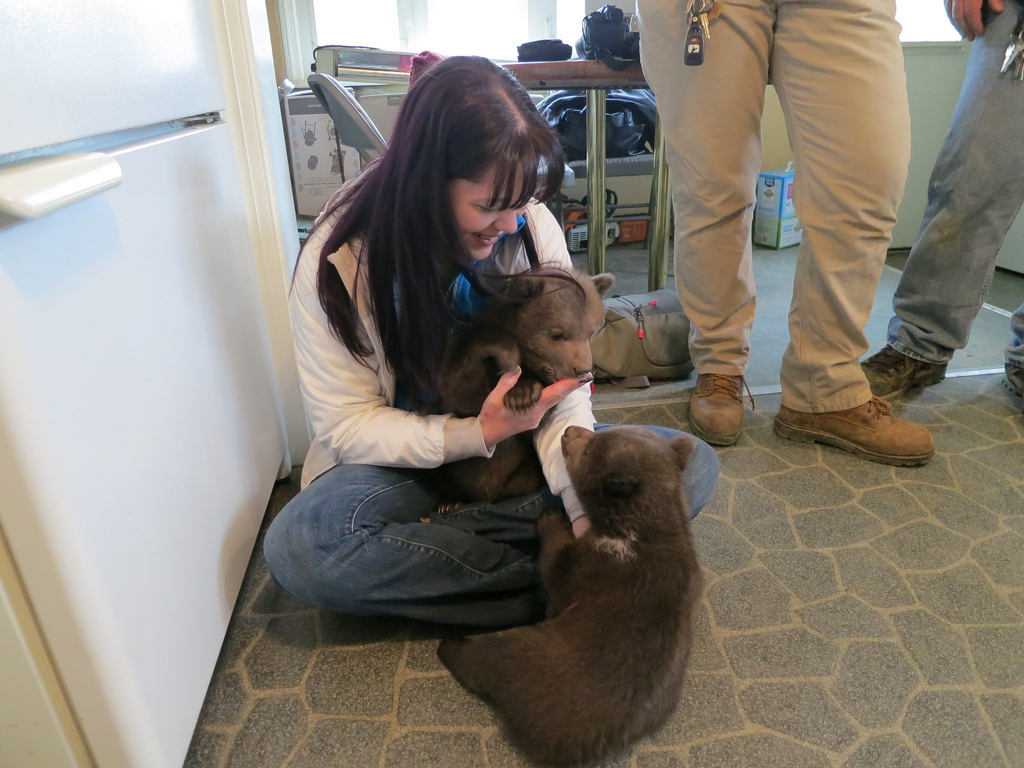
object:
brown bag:
[591, 284, 697, 388]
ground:
[183, 250, 1023, 768]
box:
[751, 162, 801, 251]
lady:
[260, 54, 599, 628]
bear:
[436, 427, 701, 767]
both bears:
[432, 248, 705, 768]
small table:
[498, 60, 670, 292]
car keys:
[677, 0, 716, 66]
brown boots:
[774, 396, 936, 467]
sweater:
[287, 157, 599, 524]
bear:
[411, 247, 614, 505]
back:
[307, 73, 390, 163]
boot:
[688, 373, 756, 446]